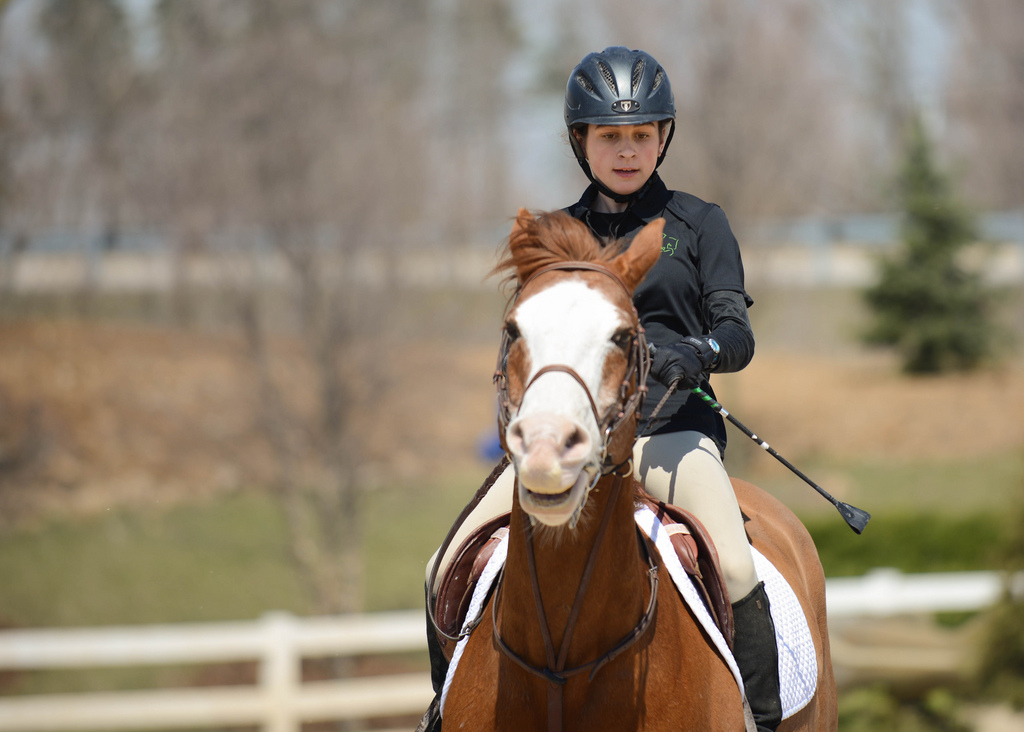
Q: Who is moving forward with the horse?
A: The lady.